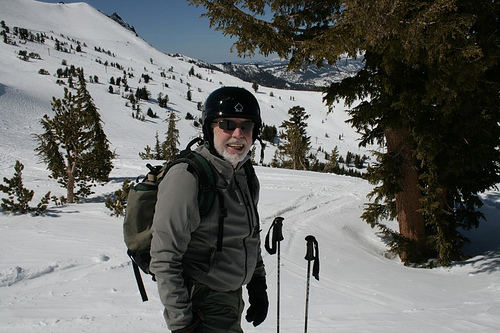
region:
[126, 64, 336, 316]
man posing for a photo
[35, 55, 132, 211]
pine tree in the snow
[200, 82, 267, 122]
black helmet on the man's head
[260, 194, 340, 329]
two ski poles in the snow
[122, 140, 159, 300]
back pack on man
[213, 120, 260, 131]
sunglasses on the man's face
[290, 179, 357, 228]
tracks in the snow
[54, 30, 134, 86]
trees on side of snow mountain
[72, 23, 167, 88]
trees on side of mountain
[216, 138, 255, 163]
moustache and beard on man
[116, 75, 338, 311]
man with ski poles posing for a photo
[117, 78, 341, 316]
man with ski poles posing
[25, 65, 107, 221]
pine tree in snow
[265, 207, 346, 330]
ski poles in snow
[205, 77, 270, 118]
helmet on man's head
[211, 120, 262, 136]
sunglasses on man's head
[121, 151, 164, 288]
gray backpack on man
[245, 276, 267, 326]
black glove on man's hand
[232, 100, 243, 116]
white logo on man's helmet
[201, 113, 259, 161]
glasses on the man's face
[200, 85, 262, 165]
a black helmet on the man's head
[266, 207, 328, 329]
two skii poles next to the man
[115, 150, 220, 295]
a backpack on the man's back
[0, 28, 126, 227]
trees in the snow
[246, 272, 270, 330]
the man has on black gloves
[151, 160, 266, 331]
the man is wearing a gray jacket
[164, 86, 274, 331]
a man looking towards the camera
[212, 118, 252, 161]
the man has a gray beard and mustache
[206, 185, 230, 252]
a black strap from the bag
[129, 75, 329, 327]
man posing for a photo on a ski mountain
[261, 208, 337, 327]
two black ski poles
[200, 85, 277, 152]
man wearing a black safety helmet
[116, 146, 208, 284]
backpack on man's back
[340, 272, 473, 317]
ground covered with white snow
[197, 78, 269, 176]
man with a white beard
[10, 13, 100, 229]
small green trees scattered on mountain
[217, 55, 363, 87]
mountains seen in the distance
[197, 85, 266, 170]
man wearing black sunglasses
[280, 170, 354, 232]
tracks in the snow from skiers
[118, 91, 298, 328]
man posing for photo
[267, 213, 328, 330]
ski poles stuck in the snow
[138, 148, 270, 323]
gray jacket of the man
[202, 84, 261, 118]
black helmet skier is wearing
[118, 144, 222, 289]
backpack skier is wearing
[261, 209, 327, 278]
black handles and strap of ski poles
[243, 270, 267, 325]
black glove of the skier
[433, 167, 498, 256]
shadow of tree on the snow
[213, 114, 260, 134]
sun glases of skier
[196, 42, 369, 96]
mountains in the background